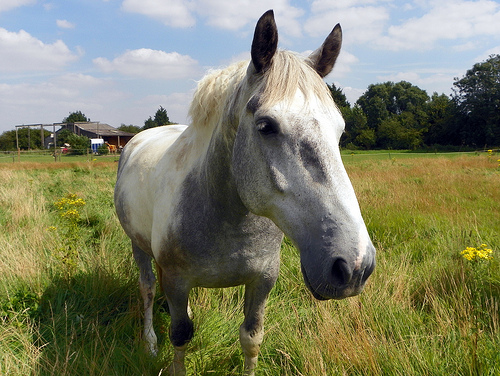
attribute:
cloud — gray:
[92, 48, 201, 85]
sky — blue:
[5, 3, 495, 128]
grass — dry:
[21, 174, 102, 275]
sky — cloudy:
[32, 0, 202, 108]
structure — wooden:
[6, 115, 104, 158]